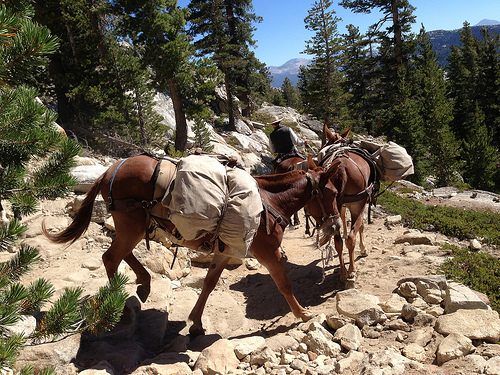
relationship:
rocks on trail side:
[179, 269, 494, 373] [2, 184, 497, 374]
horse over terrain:
[40, 124, 378, 336] [10, 146, 496, 370]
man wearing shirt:
[266, 115, 309, 163] [266, 125, 323, 157]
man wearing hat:
[256, 99, 326, 162] [272, 113, 283, 131]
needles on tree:
[42, 297, 141, 337] [4, 233, 162, 373]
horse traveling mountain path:
[40, 141, 346, 324] [24, 229, 294, 349]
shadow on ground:
[64, 283, 220, 373] [12, 272, 266, 373]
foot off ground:
[132, 274, 153, 303] [70, 244, 182, 322]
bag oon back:
[161, 154, 265, 259] [126, 149, 271, 185]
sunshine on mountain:
[282, 62, 296, 72] [266, 53, 311, 93]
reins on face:
[310, 198, 342, 234] [312, 178, 342, 245]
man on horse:
[266, 115, 309, 163] [197, 122, 320, 191]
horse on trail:
[40, 124, 378, 336] [52, 238, 413, 358]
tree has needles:
[4, 9, 134, 359] [0, 273, 142, 374]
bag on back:
[164, 153, 262, 271] [119, 151, 264, 198]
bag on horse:
[357, 134, 420, 186] [308, 118, 373, 288]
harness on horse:
[295, 171, 340, 232] [40, 124, 378, 336]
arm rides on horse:
[241, 111, 310, 181] [177, 144, 329, 200]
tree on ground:
[0, 0, 272, 374] [75, 131, 171, 176]